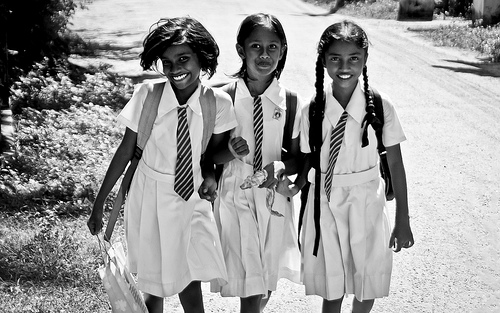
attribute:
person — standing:
[206, 12, 299, 311]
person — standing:
[87, 16, 249, 308]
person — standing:
[300, 21, 412, 310]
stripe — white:
[175, 162, 193, 179]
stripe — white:
[256, 134, 263, 154]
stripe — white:
[329, 136, 339, 156]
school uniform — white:
[281, 83, 415, 295]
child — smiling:
[293, 5, 475, 310]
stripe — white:
[176, 125, 188, 144]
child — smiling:
[308, 21, 419, 283]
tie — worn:
[243, 97, 269, 182]